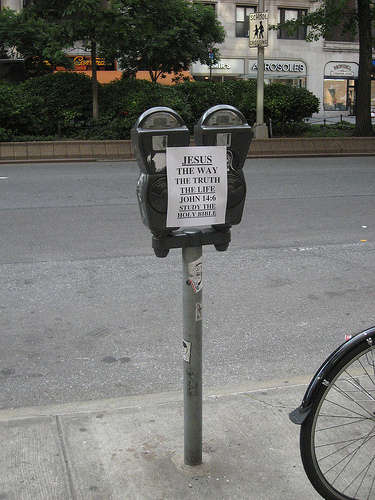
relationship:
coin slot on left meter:
[153, 134, 170, 152] [130, 102, 196, 259]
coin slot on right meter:
[215, 132, 231, 150] [197, 102, 253, 253]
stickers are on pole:
[181, 255, 206, 371] [182, 245, 204, 470]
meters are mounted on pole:
[131, 106, 250, 259] [182, 245, 204, 470]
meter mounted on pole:
[131, 106, 250, 259] [182, 245, 204, 470]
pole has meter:
[182, 245, 204, 470] [131, 106, 250, 259]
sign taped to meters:
[164, 145, 229, 229] [131, 106, 250, 259]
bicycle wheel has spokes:
[289, 324, 374, 499] [316, 353, 374, 499]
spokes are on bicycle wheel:
[316, 353, 374, 499] [289, 324, 374, 499]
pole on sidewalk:
[182, 245, 204, 470] [0, 380, 374, 497]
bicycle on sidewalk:
[289, 324, 374, 499] [0, 380, 374, 497]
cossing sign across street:
[248, 11, 271, 51] [0, 157, 372, 407]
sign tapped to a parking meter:
[164, 145, 229, 229] [132, 101, 252, 462]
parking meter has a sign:
[132, 101, 252, 462] [164, 145, 229, 229]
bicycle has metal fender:
[289, 324, 374, 499] [286, 323, 373, 426]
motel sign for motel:
[323, 59, 362, 80] [305, 0, 371, 127]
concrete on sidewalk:
[0, 0, 375, 500] [0, 380, 374, 497]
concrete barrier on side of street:
[0, 138, 375, 161] [0, 157, 372, 407]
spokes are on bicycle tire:
[316, 353, 374, 499] [289, 324, 374, 499]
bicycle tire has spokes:
[289, 324, 374, 499] [316, 353, 374, 499]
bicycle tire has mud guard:
[289, 324, 374, 499] [286, 323, 373, 426]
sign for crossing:
[247, 8, 270, 48] [248, 11, 271, 51]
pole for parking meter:
[182, 245, 204, 470] [132, 101, 252, 462]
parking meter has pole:
[132, 101, 252, 462] [182, 245, 204, 470]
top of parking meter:
[131, 103, 258, 141] [132, 101, 252, 462]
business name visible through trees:
[65, 53, 120, 70] [0, 1, 221, 121]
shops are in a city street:
[0, 1, 375, 116] [0, 157, 372, 407]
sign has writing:
[164, 145, 229, 229] [173, 156, 222, 218]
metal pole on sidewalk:
[182, 245, 204, 470] [0, 380, 374, 497]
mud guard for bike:
[286, 323, 373, 426] [289, 324, 374, 499]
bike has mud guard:
[289, 324, 374, 499] [286, 323, 373, 426]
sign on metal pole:
[247, 8, 270, 48] [255, 46, 270, 139]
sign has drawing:
[247, 8, 270, 48] [254, 20, 267, 43]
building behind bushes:
[0, 1, 375, 116] [0, 75, 323, 140]